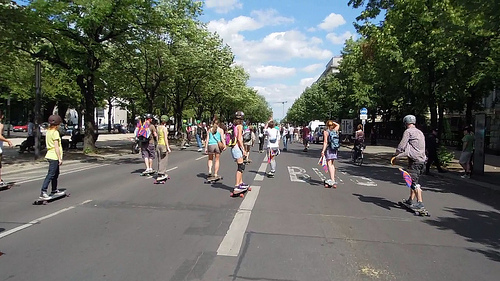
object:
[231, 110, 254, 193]
person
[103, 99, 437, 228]
road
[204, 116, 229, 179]
person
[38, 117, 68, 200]
person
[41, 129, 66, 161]
shirt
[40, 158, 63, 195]
jeans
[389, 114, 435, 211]
person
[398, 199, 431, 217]
skateboard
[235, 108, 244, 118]
helmet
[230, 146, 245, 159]
shorts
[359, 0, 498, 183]
tree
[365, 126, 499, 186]
sidewalk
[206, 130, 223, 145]
shirt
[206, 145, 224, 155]
shorts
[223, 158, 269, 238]
line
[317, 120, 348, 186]
person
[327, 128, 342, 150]
backpack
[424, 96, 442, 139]
trunk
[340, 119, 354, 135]
sign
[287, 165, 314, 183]
word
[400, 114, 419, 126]
helmet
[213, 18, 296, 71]
clouds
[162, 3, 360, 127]
sky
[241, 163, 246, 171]
pads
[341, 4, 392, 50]
sun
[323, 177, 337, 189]
skateboard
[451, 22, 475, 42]
leaves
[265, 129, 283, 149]
shirt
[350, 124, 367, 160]
person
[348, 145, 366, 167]
bike